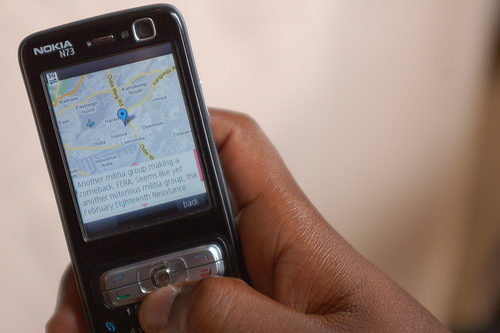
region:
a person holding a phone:
[10, 68, 413, 320]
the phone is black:
[0, 15, 263, 297]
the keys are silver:
[97, 235, 232, 316]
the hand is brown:
[147, 102, 400, 327]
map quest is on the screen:
[32, 40, 207, 210]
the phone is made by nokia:
[18, 32, 84, 62]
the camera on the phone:
[120, 13, 160, 40]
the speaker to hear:
[70, 26, 118, 46]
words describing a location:
[66, 144, 195, 224]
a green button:
[94, 285, 141, 302]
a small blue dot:
[112, 106, 130, 128]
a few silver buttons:
[90, 240, 232, 310]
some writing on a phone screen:
[75, 162, 194, 219]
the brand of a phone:
[28, 36, 80, 71]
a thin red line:
[189, 144, 209, 191]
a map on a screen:
[53, 61, 187, 165]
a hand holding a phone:
[17, 5, 442, 324]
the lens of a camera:
[126, 17, 165, 47]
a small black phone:
[16, 6, 278, 327]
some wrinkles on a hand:
[267, 221, 344, 293]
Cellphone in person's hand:
[19, 11, 429, 328]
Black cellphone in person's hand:
[19, 4, 452, 331]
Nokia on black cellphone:
[24, 33, 82, 62]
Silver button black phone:
[93, 241, 230, 308]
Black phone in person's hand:
[10, 3, 452, 332]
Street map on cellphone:
[52, 77, 226, 212]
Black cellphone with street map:
[25, 3, 446, 332]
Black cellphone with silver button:
[19, 6, 269, 318]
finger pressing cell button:
[92, 263, 302, 326]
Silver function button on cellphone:
[103, 238, 225, 316]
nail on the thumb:
[138, 275, 187, 332]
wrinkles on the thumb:
[201, 285, 245, 332]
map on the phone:
[88, 58, 178, 153]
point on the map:
[98, 98, 138, 149]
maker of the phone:
[23, 30, 83, 75]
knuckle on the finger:
[203, 105, 265, 153]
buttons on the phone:
[71, 240, 224, 322]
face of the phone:
[73, 39, 179, 266]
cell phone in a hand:
[36, 61, 309, 324]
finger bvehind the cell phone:
[67, 267, 93, 324]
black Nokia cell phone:
[15, 8, 243, 324]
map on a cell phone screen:
[46, 50, 188, 185]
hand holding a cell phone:
[17, 32, 497, 328]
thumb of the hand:
[140, 282, 310, 331]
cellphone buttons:
[102, 249, 224, 297]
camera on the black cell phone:
[127, 14, 161, 44]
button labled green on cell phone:
[105, 289, 143, 305]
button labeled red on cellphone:
[182, 264, 225, 287]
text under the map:
[70, 158, 206, 216]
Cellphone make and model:
[33, 38, 77, 61]